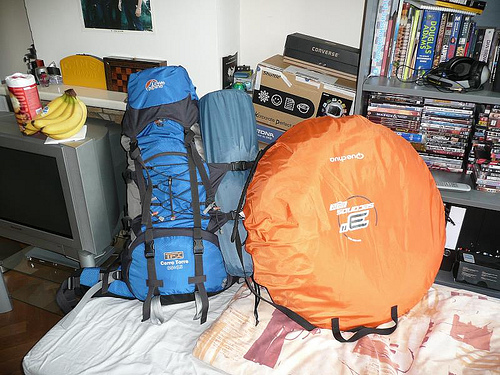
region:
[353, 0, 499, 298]
gray bookshelf with books and dvds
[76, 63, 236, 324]
blue and black camping backpack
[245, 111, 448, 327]
orange circular bag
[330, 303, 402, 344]
black handle on the orange bag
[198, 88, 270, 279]
blue sleeping pad bag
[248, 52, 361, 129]
brown cardboard box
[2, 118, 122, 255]
gray television next to the bags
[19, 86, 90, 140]
yellow bananas on the television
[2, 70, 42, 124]
red and white container on the tv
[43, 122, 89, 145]
white napkin under the bananas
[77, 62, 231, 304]
a long blue backpack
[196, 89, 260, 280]
a long blue camping gear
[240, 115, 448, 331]
round orange camping gear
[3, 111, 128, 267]
a silver TV set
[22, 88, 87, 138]
a bunch of bananas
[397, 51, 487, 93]
a set of headphones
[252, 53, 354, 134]
a brown and black cardboard box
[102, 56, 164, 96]
a wood chess board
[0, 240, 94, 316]
a two level glass table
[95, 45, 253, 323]
large blue backpack on bed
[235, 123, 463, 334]
large orange bag on bed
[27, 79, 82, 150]
bunch of yellow bananas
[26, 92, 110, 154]
bananas on television set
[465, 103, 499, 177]
stack of dvds on shelf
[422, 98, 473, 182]
stack of dvds on shelf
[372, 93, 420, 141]
stack of dvds on shelf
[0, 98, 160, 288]
grey small television set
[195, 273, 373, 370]
blanket on the bed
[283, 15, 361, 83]
brown and black box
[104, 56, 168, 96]
a black and brown checker set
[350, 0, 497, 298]
a grey shelf with books and dvd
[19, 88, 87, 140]
a large bunch of ripe yellow bananas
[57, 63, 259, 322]
a large blue weather resistant back pack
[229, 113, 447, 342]
a large orange weather resistant backpack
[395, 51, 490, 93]
a grey and black wired headset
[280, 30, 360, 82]
a black shoe box stacked against the wall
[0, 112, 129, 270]
a medium sized silver television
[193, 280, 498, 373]
a pillow case with an abstract design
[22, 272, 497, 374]
a small bed covered in a white sheet